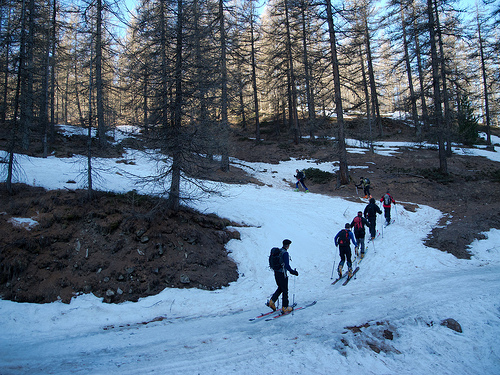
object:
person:
[265, 238, 299, 314]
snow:
[0, 149, 499, 373]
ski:
[265, 304, 296, 322]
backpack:
[268, 247, 284, 272]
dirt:
[1, 180, 261, 305]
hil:
[0, 118, 499, 375]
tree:
[133, 0, 226, 206]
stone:
[179, 274, 191, 285]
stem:
[170, 1, 184, 208]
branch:
[179, 176, 246, 201]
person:
[293, 169, 310, 193]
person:
[355, 176, 375, 199]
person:
[378, 190, 395, 224]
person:
[364, 198, 382, 239]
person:
[349, 211, 372, 257]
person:
[334, 223, 358, 278]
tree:
[305, 0, 373, 184]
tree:
[398, 0, 468, 176]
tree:
[275, 2, 305, 143]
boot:
[280, 305, 293, 313]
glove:
[290, 268, 298, 276]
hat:
[281, 239, 294, 246]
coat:
[275, 247, 293, 276]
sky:
[0, 0, 498, 78]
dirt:
[381, 151, 499, 183]